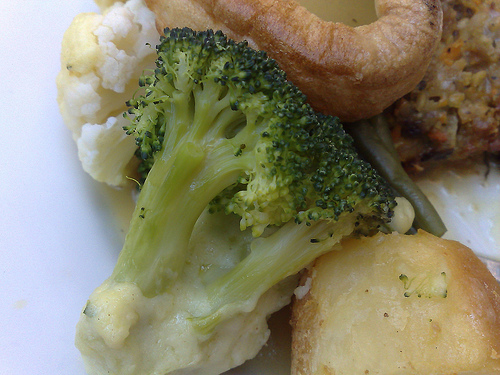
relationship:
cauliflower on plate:
[76, 26, 397, 371] [0, 0, 497, 372]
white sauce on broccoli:
[99, 278, 262, 367] [75, 70, 405, 328]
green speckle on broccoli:
[269, 141, 308, 197] [96, 25, 395, 365]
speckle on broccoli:
[322, 179, 335, 193] [96, 25, 395, 365]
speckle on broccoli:
[352, 172, 364, 184] [36, 55, 386, 312]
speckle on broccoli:
[288, 160, 306, 174] [73, 28, 398, 374]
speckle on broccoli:
[331, 137, 343, 167] [96, 25, 395, 365]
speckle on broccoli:
[157, 29, 395, 220] [83, 25, 387, 347]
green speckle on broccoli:
[269, 90, 301, 115] [64, 55, 399, 374]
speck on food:
[397, 269, 413, 297] [282, 232, 494, 374]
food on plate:
[40, 0, 493, 373] [0, 0, 497, 372]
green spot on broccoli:
[137, 207, 145, 220] [96, 25, 395, 365]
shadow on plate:
[76, 163, 122, 260] [2, 1, 126, 373]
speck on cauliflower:
[63, 61, 75, 74] [48, 0, 158, 190]